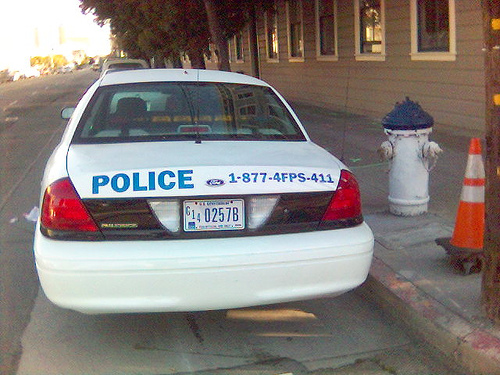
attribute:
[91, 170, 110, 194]
letter — blue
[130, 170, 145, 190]
letter — blue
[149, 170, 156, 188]
letter — blue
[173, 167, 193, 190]
letter — blue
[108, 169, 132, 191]
letter — blue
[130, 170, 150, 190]
letter — blue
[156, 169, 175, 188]
letter — blue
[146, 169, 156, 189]
letter — blue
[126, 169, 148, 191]
letter — blue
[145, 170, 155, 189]
letter — blue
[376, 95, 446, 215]
fire hydrant — blue, white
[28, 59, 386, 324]
car — police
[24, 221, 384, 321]
bumper — white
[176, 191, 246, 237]
plate — license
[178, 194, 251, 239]
plate — license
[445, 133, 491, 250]
cone — orange, safety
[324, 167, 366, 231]
light — brake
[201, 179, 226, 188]
logo — ford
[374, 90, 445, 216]
hydrant — white, blue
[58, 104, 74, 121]
mirror — side view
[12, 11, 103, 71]
sky — daytime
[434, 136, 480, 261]
cone — orange, white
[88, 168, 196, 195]
letters — blue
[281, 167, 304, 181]
letters — blue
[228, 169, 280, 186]
numbers — blue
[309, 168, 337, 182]
numbers — blue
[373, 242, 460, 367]
curb paint — worn, red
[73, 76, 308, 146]
window — back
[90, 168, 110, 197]
letter — p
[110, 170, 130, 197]
letter — blue